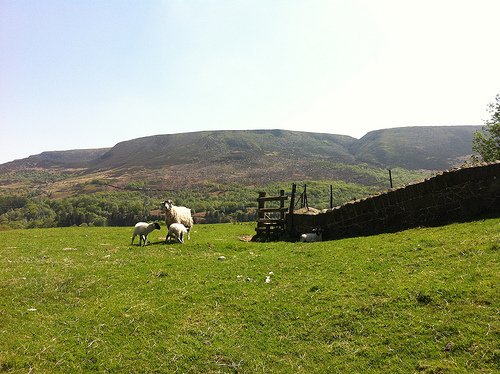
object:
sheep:
[159, 199, 193, 238]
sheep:
[164, 223, 193, 245]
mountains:
[102, 123, 354, 167]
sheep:
[129, 219, 160, 246]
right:
[478, 6, 500, 372]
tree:
[463, 94, 499, 162]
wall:
[371, 181, 496, 235]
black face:
[155, 223, 161, 230]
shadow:
[147, 237, 177, 247]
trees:
[125, 179, 143, 190]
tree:
[68, 208, 95, 226]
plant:
[4, 254, 15, 264]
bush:
[11, 201, 54, 227]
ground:
[51, 228, 89, 243]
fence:
[256, 191, 286, 240]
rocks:
[373, 196, 381, 204]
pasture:
[9, 226, 477, 361]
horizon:
[7, 125, 486, 146]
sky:
[364, 1, 496, 117]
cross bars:
[276, 188, 289, 203]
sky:
[2, 4, 306, 110]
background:
[0, 4, 497, 154]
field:
[6, 264, 499, 371]